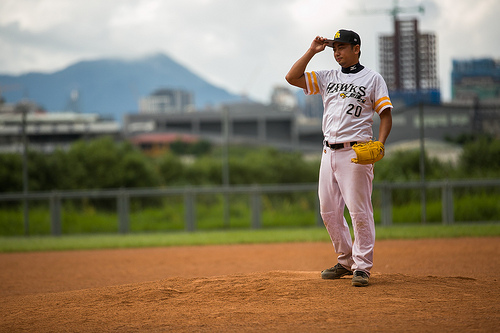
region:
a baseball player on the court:
[284, 22, 384, 288]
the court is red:
[0, 232, 498, 327]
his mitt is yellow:
[351, 136, 386, 164]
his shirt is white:
[294, 66, 385, 146]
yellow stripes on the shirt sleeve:
[372, 97, 388, 110]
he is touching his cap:
[303, 29, 368, 54]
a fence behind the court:
[0, 173, 492, 230]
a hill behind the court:
[6, 42, 263, 114]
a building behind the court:
[370, 14, 441, 93]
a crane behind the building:
[341, 0, 432, 26]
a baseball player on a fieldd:
[279, 15, 402, 290]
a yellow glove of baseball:
[346, 130, 390, 172]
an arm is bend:
[283, 22, 329, 99]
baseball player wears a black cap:
[281, 20, 391, 114]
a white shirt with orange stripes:
[305, 62, 395, 148]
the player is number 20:
[279, 19, 404, 284]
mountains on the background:
[3, 38, 255, 110]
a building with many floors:
[371, 5, 458, 114]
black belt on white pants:
[317, 133, 360, 154]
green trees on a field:
[0, 129, 495, 212]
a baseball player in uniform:
[279, 18, 408, 288]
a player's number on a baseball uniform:
[340, 98, 365, 119]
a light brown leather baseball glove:
[342, 138, 389, 170]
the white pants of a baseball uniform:
[311, 138, 391, 274]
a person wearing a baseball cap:
[302, 21, 369, 68]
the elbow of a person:
[282, 63, 302, 91]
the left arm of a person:
[377, 105, 399, 145]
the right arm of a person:
[290, 38, 312, 94]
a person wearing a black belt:
[317, 133, 372, 154]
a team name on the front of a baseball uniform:
[322, 78, 373, 102]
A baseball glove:
[348, 138, 387, 168]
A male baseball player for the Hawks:
[283, 29, 392, 289]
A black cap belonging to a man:
[322, 28, 364, 47]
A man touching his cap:
[270, 28, 364, 91]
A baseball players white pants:
[314, 143, 376, 272]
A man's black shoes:
[318, 264, 371, 286]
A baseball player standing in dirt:
[282, 30, 492, 319]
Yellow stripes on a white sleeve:
[371, 75, 396, 116]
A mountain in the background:
[3, 45, 264, 110]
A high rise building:
[376, 14, 442, 103]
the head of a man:
[316, 18, 381, 88]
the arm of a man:
[270, 16, 350, 104]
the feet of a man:
[319, 225, 404, 290]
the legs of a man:
[296, 123, 421, 268]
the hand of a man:
[302, 34, 329, 66]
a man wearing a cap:
[294, 25, 374, 87]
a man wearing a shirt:
[284, 15, 419, 156]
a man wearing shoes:
[306, 234, 427, 299]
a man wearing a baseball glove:
[296, 112, 443, 190]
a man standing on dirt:
[271, 0, 455, 291]